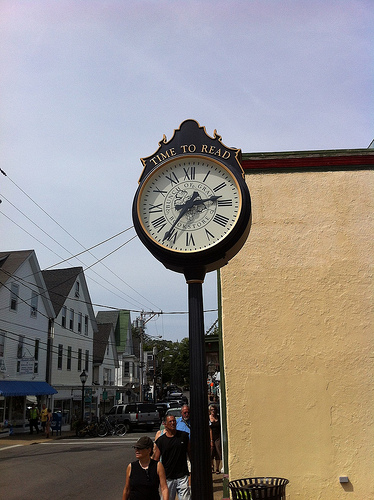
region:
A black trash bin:
[228, 476, 290, 498]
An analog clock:
[132, 117, 253, 275]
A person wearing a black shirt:
[158, 431, 191, 477]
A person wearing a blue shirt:
[175, 415, 192, 434]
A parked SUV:
[106, 403, 159, 433]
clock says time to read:
[131, 116, 254, 497]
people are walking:
[121, 404, 220, 498]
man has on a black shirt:
[121, 435, 170, 497]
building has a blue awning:
[0, 379, 56, 396]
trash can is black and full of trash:
[226, 474, 289, 498]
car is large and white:
[105, 403, 161, 428]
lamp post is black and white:
[80, 369, 89, 427]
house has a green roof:
[112, 310, 139, 402]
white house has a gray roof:
[39, 266, 98, 417]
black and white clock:
[135, 130, 252, 273]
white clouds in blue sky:
[21, 28, 64, 71]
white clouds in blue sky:
[90, 38, 142, 77]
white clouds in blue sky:
[40, 101, 84, 144]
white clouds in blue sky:
[63, 178, 110, 230]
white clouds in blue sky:
[154, 27, 199, 70]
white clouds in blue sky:
[223, 17, 271, 68]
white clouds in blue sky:
[298, 2, 341, 45]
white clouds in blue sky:
[257, 68, 298, 119]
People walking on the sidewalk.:
[140, 403, 187, 491]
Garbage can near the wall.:
[229, 466, 288, 494]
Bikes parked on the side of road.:
[73, 410, 136, 435]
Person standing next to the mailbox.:
[39, 402, 68, 437]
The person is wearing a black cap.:
[138, 433, 160, 452]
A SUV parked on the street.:
[107, 398, 164, 432]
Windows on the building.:
[59, 341, 102, 373]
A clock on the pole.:
[117, 138, 253, 269]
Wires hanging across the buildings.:
[72, 279, 203, 320]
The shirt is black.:
[156, 438, 186, 478]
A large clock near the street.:
[130, 118, 252, 498]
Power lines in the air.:
[1, 166, 159, 316]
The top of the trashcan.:
[226, 476, 290, 498]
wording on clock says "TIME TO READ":
[132, 120, 254, 273]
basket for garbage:
[224, 476, 285, 498]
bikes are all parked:
[70, 412, 129, 438]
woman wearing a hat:
[117, 436, 169, 499]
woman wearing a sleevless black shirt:
[119, 437, 168, 498]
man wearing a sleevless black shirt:
[154, 412, 191, 499]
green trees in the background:
[133, 328, 222, 402]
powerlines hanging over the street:
[0, 166, 220, 317]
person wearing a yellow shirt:
[38, 401, 50, 433]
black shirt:
[159, 440, 185, 475]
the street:
[66, 462, 92, 486]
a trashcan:
[234, 476, 282, 498]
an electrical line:
[96, 233, 124, 257]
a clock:
[139, 150, 245, 254]